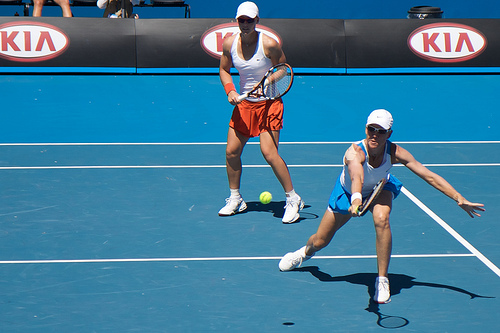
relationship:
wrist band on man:
[349, 189, 354, 206] [278, 110, 485, 301]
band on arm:
[223, 82, 237, 95] [218, 36, 243, 105]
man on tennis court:
[214, 3, 306, 221] [26, 86, 321, 293]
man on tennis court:
[278, 109, 488, 304] [0, 73, 499, 332]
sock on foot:
[284, 186, 299, 200] [280, 194, 305, 224]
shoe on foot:
[282, 196, 307, 224] [280, 194, 305, 224]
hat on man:
[363, 106, 393, 131] [278, 109, 488, 304]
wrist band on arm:
[223, 82, 237, 95] [225, 75, 240, 102]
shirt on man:
[229, 31, 279, 102] [214, 0, 308, 225]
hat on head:
[233, 0, 259, 22] [233, 2, 262, 34]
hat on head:
[363, 106, 393, 131] [366, 107, 396, 149]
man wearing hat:
[278, 109, 488, 304] [352, 107, 397, 132]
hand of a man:
[458, 196, 486, 219] [278, 110, 485, 301]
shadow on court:
[296, 264, 493, 327] [5, 73, 498, 330]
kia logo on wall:
[1, 20, 70, 62] [2, 14, 499, 77]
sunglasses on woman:
[235, 17, 257, 24] [278, 111, 487, 306]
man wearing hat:
[214, 0, 308, 225] [228, 1, 260, 22]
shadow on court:
[243, 200, 284, 220] [0, 73, 499, 330]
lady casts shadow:
[273, 107, 484, 308] [243, 200, 284, 220]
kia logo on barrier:
[1, 20, 70, 62] [1, 17, 500, 73]